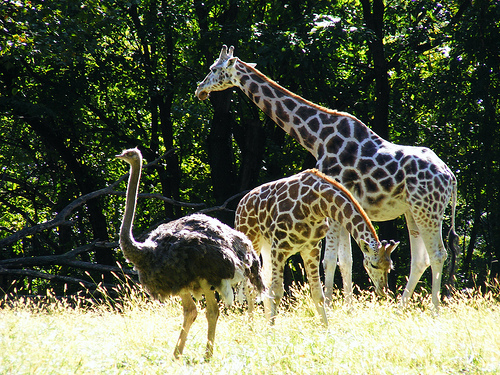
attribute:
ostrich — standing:
[113, 146, 267, 366]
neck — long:
[118, 161, 142, 264]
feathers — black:
[167, 234, 275, 304]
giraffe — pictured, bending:
[193, 41, 458, 310]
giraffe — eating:
[230, 165, 396, 326]